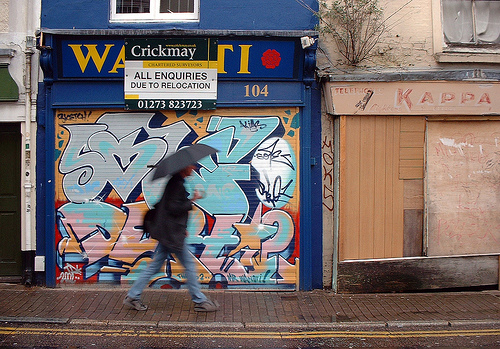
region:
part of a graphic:
[262, 247, 277, 274]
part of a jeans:
[181, 268, 201, 291]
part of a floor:
[253, 295, 268, 310]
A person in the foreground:
[110, 137, 252, 320]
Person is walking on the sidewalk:
[98, 145, 253, 317]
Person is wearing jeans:
[118, 231, 230, 314]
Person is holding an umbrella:
[132, 131, 234, 191]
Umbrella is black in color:
[135, 133, 225, 204]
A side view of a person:
[107, 153, 222, 312]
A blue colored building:
[37, 3, 322, 288]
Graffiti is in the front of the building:
[53, 110, 299, 288]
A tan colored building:
[320, 0, 499, 287]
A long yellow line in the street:
[2, 313, 499, 347]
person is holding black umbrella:
[134, 137, 211, 200]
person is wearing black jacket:
[150, 166, 187, 246]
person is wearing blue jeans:
[112, 245, 213, 307]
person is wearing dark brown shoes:
[115, 281, 235, 306]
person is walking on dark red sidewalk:
[51, 276, 471, 338]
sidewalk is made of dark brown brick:
[84, 286, 465, 333]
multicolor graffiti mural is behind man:
[46, 104, 316, 294]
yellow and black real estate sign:
[120, 38, 218, 125]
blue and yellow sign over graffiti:
[46, 35, 306, 86]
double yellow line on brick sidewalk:
[44, 312, 486, 342]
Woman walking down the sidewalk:
[109, 146, 238, 318]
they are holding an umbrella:
[144, 143, 209, 305]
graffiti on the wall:
[61, 150, 130, 247]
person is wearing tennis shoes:
[120, 283, 157, 320]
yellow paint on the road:
[127, 320, 178, 346]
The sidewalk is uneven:
[279, 282, 366, 331]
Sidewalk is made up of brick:
[73, 286, 122, 323]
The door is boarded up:
[412, 122, 490, 255]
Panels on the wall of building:
[357, 126, 427, 256]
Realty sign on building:
[102, 36, 237, 117]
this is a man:
[136, 150, 223, 307]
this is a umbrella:
[161, 150, 202, 176]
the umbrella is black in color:
[175, 149, 195, 168]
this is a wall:
[439, 126, 494, 254]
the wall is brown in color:
[459, 150, 497, 267]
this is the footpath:
[255, 285, 407, 339]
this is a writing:
[134, 67, 213, 92]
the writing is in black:
[129, 67, 211, 92]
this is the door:
[346, 117, 426, 245]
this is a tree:
[328, 6, 371, 55]